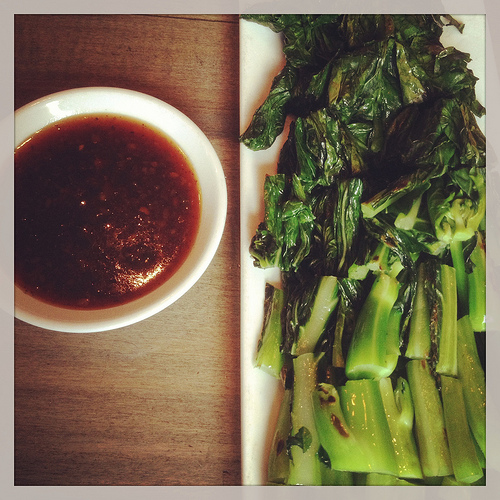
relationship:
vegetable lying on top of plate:
[434, 262, 461, 379] [237, 13, 485, 483]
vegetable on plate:
[314, 376, 424, 482] [237, 13, 485, 483]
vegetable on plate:
[434, 262, 461, 379] [237, 13, 485, 483]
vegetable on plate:
[434, 262, 461, 379] [238, 1, 499, 499]